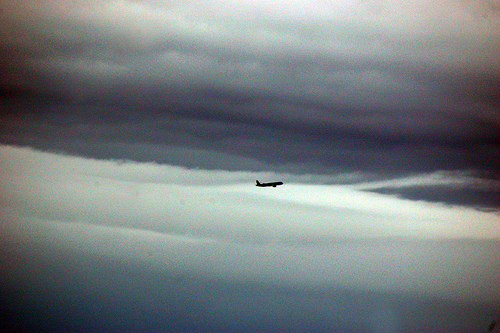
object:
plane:
[255, 179, 284, 187]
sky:
[0, 0, 500, 332]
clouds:
[4, 0, 497, 185]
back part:
[255, 179, 270, 187]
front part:
[271, 181, 284, 187]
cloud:
[352, 179, 498, 215]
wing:
[272, 184, 277, 187]